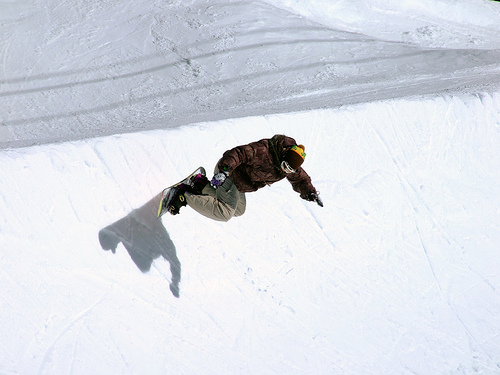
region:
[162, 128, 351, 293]
the man is snowboarding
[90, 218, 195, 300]
shadow of the man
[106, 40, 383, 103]
tracks on the snow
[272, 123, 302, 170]
hat on the head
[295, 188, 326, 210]
glove on the hand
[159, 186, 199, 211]
shoes on the feet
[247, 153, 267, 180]
the jacket is brown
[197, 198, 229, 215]
the pants are tan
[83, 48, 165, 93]
the snow is shadowed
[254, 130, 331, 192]
the head of a man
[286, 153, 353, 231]
the hand of a man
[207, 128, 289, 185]
the arm of a man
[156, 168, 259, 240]
the legs of a man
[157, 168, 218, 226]
the foot of a man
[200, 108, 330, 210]
a man wearing a coat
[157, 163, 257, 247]
a man wearing pants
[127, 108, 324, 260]
a man in the snow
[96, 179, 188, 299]
The man's shadow is on the snow.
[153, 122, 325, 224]
The man is snowboarding down the slope.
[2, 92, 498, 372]
The snow is bright and white.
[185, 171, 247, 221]
The snowboarder is wearing brown pants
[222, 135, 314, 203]
The snowboard is wearing a brown, thick jacket.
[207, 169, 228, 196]
The gloved hand of the snowboarder.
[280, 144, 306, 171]
The multicolored knit cap of the snowboarder.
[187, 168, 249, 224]
The snowboarder's legs are bent.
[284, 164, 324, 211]
The outstretched arm of the snowboarder.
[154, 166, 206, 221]
The feet are touching the snowboard.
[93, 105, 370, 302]
Only one person in the shot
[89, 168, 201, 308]
Shadow on the ground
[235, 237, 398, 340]
Snow is in the picture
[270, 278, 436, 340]
The ground is white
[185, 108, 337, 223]
The coat is brown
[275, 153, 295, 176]
He is wearing white googles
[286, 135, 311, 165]
The hat is multi-colored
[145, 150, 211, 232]
Surfing on the board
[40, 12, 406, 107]
Shadow in the back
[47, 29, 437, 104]
Lines on the ground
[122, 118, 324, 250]
this fella is snowboarding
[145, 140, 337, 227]
he is airborn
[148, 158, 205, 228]
the board appears to be yellow or multicolored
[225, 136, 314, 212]
his jacket is brown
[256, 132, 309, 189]
he is wearing a knitted boggan cap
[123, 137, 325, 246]
he appears very focused on the ride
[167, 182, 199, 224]
his sneakers are black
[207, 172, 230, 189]
he is wearing gloves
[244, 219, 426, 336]
the snow appears to be quite deep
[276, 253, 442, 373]
the snow is blindingly white